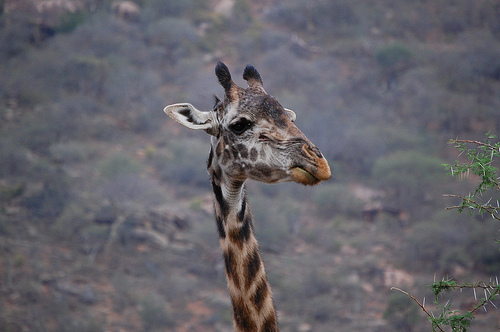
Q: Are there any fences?
A: No, there are no fences.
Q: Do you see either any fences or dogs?
A: No, there are no fences or dogs.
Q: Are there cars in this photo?
A: No, there are no cars.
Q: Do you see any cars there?
A: No, there are no cars.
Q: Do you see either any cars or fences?
A: No, there are no cars or fences.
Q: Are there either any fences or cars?
A: No, there are no cars or fences.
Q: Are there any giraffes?
A: Yes, there is a giraffe.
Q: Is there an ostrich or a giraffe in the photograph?
A: Yes, there is a giraffe.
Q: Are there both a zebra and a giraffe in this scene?
A: No, there is a giraffe but no zebras.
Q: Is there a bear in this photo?
A: No, there are no bears.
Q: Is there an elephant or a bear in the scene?
A: No, there are no bears or elephants.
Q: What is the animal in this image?
A: The animal is a giraffe.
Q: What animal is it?
A: The animal is a giraffe.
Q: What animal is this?
A: That is a giraffe.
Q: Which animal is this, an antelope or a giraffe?
A: That is a giraffe.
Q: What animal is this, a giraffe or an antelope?
A: That is a giraffe.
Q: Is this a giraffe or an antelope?
A: This is a giraffe.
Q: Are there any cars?
A: No, there are no cars.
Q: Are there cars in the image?
A: No, there are no cars.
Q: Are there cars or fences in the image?
A: No, there are no cars or fences.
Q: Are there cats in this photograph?
A: No, there are no cats.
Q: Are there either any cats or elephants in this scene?
A: No, there are no cats or elephants.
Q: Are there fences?
A: No, there are no fences.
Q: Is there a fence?
A: No, there are no fences.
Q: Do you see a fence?
A: No, there are no fences.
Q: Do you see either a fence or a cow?
A: No, there are no fences or cows.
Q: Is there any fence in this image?
A: No, there are no fences.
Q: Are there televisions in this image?
A: Yes, there is a television.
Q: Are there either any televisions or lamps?
A: Yes, there is a television.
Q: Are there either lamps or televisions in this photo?
A: Yes, there is a television.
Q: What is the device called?
A: The device is a television.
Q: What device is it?
A: The device is a television.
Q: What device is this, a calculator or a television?
A: That is a television.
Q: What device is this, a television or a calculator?
A: That is a television.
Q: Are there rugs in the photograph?
A: No, there are no rugs.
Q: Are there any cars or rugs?
A: No, there are no rugs or cars.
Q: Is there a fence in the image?
A: No, there are no fences.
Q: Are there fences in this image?
A: No, there are no fences.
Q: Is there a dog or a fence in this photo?
A: No, there are no fences or dogs.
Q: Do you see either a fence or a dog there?
A: No, there are no fences or dogs.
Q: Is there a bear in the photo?
A: No, there are no bears.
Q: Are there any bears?
A: No, there are no bears.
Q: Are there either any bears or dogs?
A: No, there are no bears or dogs.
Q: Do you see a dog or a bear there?
A: No, there are no bears or dogs.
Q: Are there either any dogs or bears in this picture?
A: No, there are no bears or dogs.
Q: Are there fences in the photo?
A: No, there are no fences.